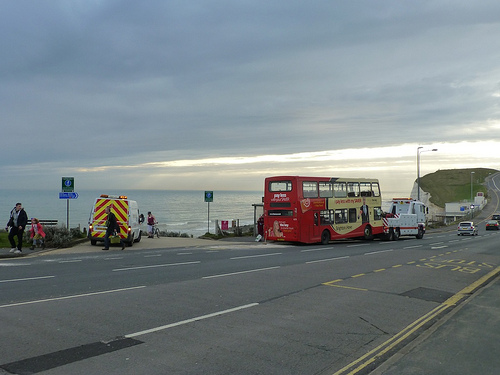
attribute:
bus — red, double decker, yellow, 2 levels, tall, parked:
[255, 170, 390, 252]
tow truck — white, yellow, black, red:
[381, 191, 434, 244]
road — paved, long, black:
[0, 165, 499, 373]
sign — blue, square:
[56, 174, 82, 203]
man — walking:
[3, 200, 29, 256]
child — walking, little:
[25, 215, 49, 254]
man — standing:
[144, 209, 157, 240]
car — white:
[452, 217, 482, 240]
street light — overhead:
[414, 143, 444, 205]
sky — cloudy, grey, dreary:
[2, 0, 499, 191]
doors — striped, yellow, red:
[93, 199, 130, 241]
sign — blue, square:
[199, 188, 220, 207]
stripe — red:
[386, 220, 421, 234]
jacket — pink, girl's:
[24, 220, 50, 243]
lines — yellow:
[312, 247, 497, 375]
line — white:
[121, 297, 265, 343]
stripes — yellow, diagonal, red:
[92, 197, 130, 244]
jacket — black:
[3, 206, 31, 230]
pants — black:
[5, 225, 27, 253]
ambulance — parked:
[84, 190, 146, 248]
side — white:
[412, 181, 444, 226]